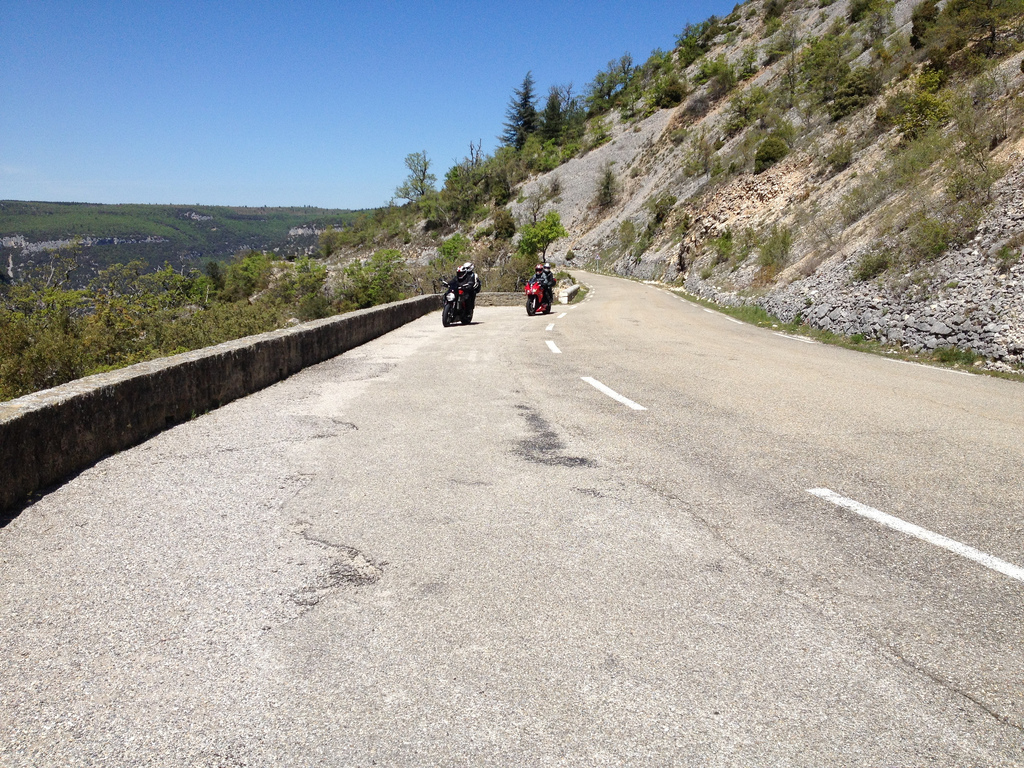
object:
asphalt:
[0, 266, 1024, 768]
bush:
[851, 236, 897, 283]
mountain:
[252, 0, 1024, 384]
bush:
[896, 213, 973, 300]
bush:
[939, 113, 1007, 213]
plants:
[0, 204, 570, 404]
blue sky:
[0, 0, 759, 210]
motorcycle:
[521, 278, 557, 316]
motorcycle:
[443, 280, 476, 327]